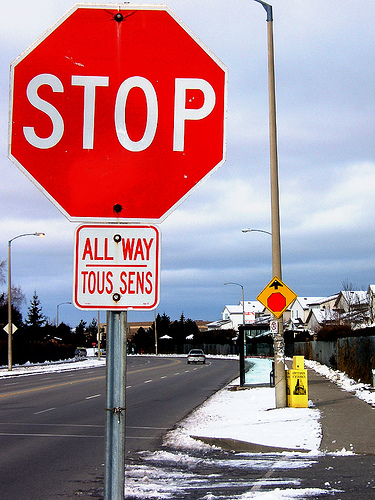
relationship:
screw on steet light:
[114, 11, 125, 22] [32, 229, 47, 239]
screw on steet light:
[113, 204, 122, 213] [32, 229, 47, 239]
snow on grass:
[208, 389, 288, 428] [182, 351, 321, 454]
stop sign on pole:
[10, 3, 233, 222] [104, 311, 126, 496]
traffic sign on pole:
[254, 272, 301, 321] [264, 2, 290, 406]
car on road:
[187, 348, 204, 363] [2, 356, 250, 495]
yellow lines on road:
[2, 378, 85, 398] [5, 332, 208, 484]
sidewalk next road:
[308, 402, 374, 455] [158, 387, 193, 421]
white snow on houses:
[205, 283, 374, 330] [204, 287, 373, 328]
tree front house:
[335, 279, 363, 332] [328, 286, 363, 315]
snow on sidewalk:
[331, 438, 359, 456] [330, 408, 362, 429]